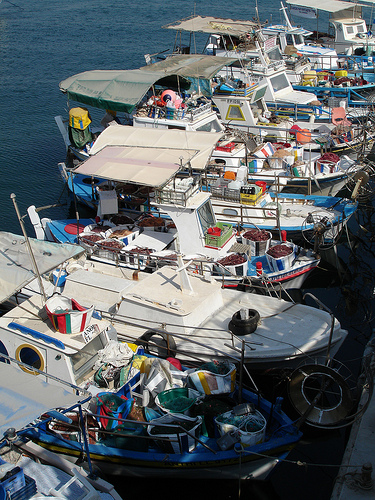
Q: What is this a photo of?
A: Boats.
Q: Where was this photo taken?
A: At a dock.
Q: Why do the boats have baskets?
A: For carrying things.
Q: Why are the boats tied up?
A: So they do not float away.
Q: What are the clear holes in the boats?
A: Windows.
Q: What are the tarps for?
A: A roof.